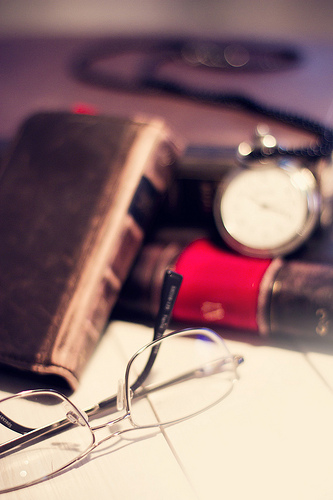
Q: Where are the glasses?
A: On the table.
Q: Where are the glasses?
A: On a table.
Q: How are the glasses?
A: Upside down.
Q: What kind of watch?
A: Pocket.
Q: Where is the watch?
A: On top of book.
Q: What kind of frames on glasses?
A: Wire.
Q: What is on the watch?
A: Black chain.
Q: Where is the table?
A: Under the glasses.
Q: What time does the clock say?
A: 10:20.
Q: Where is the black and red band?
A: On the edge.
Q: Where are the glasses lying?
A: On Table.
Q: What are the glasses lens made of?
A: Glass.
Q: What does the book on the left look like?
A: Brown and black.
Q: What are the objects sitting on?
A: Table.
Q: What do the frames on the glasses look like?
A: Silver.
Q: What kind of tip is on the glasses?
A: Rubber.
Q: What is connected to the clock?
A: Strap.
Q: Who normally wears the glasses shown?
A: A man.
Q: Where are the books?
A: On a desk.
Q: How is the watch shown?
A: On one of the books.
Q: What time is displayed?
A: 10:20.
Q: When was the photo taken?
A: 10:20.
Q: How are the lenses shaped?
A: Square.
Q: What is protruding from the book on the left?
A: A bookmarker.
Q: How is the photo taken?
A: Out of focus.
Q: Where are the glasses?
A: On the desk.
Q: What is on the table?
A: Several objects.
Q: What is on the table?
A: Glasses.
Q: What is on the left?
A: A book.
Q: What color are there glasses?
A: Black.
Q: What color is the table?
A: White.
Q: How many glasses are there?
A: One.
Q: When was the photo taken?
A: Day time.